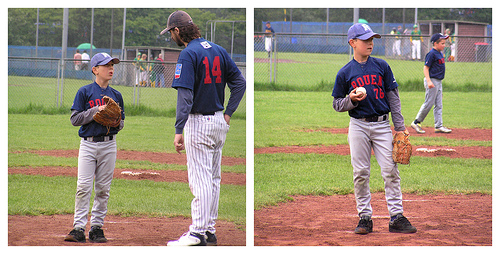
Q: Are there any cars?
A: No, there are no cars.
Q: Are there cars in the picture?
A: No, there are no cars.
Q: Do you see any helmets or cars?
A: No, there are no cars or helmets.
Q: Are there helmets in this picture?
A: No, there are no helmets.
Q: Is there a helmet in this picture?
A: No, there are no helmets.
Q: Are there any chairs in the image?
A: No, there are no chairs.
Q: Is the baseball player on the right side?
A: Yes, the player is on the right of the image.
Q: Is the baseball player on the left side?
A: No, the player is on the right of the image.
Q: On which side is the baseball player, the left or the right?
A: The player is on the right of the image.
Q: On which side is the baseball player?
A: The player is on the right of the image.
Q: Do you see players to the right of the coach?
A: Yes, there is a player to the right of the coach.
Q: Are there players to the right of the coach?
A: Yes, there is a player to the right of the coach.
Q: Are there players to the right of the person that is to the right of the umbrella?
A: Yes, there is a player to the right of the coach.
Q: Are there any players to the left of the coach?
A: No, the player is to the right of the coach.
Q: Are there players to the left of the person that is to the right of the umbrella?
A: No, the player is to the right of the coach.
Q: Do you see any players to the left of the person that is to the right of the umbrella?
A: No, the player is to the right of the coach.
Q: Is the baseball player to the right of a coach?
A: Yes, the player is to the right of a coach.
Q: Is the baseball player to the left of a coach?
A: No, the player is to the right of a coach.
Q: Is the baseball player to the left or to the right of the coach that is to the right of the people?
A: The player is to the right of the coach.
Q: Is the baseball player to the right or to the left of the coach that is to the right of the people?
A: The player is to the right of the coach.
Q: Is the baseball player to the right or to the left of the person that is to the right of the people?
A: The player is to the right of the coach.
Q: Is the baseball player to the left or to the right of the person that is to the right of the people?
A: The player is to the right of the coach.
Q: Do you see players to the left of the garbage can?
A: Yes, there is a player to the left of the garbage can.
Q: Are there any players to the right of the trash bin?
A: No, the player is to the left of the trash bin.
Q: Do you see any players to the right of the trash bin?
A: No, the player is to the left of the trash bin.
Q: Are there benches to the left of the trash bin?
A: No, there is a player to the left of the trash bin.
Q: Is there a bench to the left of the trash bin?
A: No, there is a player to the left of the trash bin.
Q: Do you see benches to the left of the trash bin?
A: No, there is a player to the left of the trash bin.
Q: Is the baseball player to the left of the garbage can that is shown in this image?
A: Yes, the player is to the left of the garbage can.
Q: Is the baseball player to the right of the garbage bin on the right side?
A: No, the player is to the left of the trash bin.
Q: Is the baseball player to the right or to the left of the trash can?
A: The player is to the left of the trash can.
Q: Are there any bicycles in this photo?
A: No, there are no bicycles.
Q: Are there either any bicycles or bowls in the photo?
A: No, there are no bicycles or bowls.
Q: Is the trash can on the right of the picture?
A: Yes, the trash can is on the right of the image.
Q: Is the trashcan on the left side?
A: No, the trashcan is on the right of the image.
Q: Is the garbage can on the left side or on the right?
A: The garbage can is on the right of the image.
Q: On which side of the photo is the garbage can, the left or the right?
A: The garbage can is on the right of the image.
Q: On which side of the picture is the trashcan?
A: The trashcan is on the right of the image.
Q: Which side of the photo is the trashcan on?
A: The trashcan is on the right of the image.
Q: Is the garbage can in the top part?
A: Yes, the garbage can is in the top of the image.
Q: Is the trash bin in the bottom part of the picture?
A: No, the trash bin is in the top of the image.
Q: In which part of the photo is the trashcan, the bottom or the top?
A: The trashcan is in the top of the image.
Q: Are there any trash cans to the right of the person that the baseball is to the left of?
A: Yes, there is a trash can to the right of the person.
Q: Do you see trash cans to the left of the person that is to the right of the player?
A: No, the trash can is to the right of the person.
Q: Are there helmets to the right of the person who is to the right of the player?
A: No, there is a trash can to the right of the person.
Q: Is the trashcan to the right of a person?
A: Yes, the trashcan is to the right of a person.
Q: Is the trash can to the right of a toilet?
A: No, the trash can is to the right of a person.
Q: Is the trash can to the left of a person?
A: No, the trash can is to the right of a person.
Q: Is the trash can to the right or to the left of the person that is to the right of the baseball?
A: The trash can is to the right of the person.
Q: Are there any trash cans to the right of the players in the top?
A: Yes, there is a trash can to the right of the players.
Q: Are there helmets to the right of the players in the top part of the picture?
A: No, there is a trash can to the right of the players.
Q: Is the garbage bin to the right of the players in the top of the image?
A: Yes, the garbage bin is to the right of the players.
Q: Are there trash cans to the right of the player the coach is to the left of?
A: Yes, there is a trash can to the right of the player.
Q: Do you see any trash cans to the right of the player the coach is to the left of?
A: Yes, there is a trash can to the right of the player.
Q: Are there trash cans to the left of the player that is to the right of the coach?
A: No, the trash can is to the right of the player.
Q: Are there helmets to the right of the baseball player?
A: No, there is a trash can to the right of the player.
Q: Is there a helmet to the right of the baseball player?
A: No, there is a trash can to the right of the player.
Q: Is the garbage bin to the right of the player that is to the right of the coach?
A: Yes, the garbage bin is to the right of the player.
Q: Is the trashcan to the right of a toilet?
A: No, the trashcan is to the right of the player.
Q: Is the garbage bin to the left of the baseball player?
A: No, the garbage bin is to the right of the player.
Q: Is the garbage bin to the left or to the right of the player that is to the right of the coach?
A: The garbage bin is to the right of the player.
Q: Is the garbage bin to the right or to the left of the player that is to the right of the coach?
A: The garbage bin is to the right of the player.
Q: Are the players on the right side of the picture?
A: Yes, the players are on the right of the image.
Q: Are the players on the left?
A: No, the players are on the right of the image.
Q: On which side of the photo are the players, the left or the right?
A: The players are on the right of the image.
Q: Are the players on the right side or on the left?
A: The players are on the right of the image.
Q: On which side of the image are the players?
A: The players are on the right of the image.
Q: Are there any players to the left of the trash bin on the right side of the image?
A: Yes, there are players to the left of the trash can.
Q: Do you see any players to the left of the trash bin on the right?
A: Yes, there are players to the left of the trash can.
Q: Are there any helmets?
A: No, there are no helmets.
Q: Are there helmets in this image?
A: No, there are no helmets.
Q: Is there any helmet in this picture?
A: No, there are no helmets.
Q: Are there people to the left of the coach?
A: Yes, there is a person to the left of the coach.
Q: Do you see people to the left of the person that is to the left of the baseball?
A: Yes, there is a person to the left of the coach.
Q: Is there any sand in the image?
A: Yes, there is sand.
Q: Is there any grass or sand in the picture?
A: Yes, there is sand.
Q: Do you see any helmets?
A: No, there are no helmets.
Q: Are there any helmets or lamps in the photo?
A: No, there are no helmets or lamps.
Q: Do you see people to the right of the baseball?
A: Yes, there is a person to the right of the baseball.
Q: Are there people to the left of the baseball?
A: No, the person is to the right of the baseball.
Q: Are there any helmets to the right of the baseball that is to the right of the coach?
A: No, there is a person to the right of the baseball.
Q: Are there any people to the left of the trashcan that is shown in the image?
A: Yes, there is a person to the left of the trashcan.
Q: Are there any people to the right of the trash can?
A: No, the person is to the left of the trash can.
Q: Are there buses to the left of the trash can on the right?
A: No, there is a person to the left of the trash can.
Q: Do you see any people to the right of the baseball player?
A: Yes, there is a person to the right of the player.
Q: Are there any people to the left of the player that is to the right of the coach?
A: No, the person is to the right of the player.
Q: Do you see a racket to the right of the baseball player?
A: No, there is a person to the right of the player.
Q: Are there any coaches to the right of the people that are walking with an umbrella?
A: Yes, there is a coach to the right of the people.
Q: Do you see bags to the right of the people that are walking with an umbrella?
A: No, there is a coach to the right of the people.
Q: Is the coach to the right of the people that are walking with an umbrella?
A: Yes, the coach is to the right of the people.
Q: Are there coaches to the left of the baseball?
A: Yes, there is a coach to the left of the baseball.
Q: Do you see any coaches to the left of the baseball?
A: Yes, there is a coach to the left of the baseball.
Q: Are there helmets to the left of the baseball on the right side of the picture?
A: No, there is a coach to the left of the baseball.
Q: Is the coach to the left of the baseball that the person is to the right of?
A: Yes, the coach is to the left of the baseball.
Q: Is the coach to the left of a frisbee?
A: No, the coach is to the left of the baseball.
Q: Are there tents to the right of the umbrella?
A: No, there is a coach to the right of the umbrella.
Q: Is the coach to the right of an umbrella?
A: Yes, the coach is to the right of an umbrella.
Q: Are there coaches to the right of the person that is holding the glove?
A: Yes, there is a coach to the right of the person.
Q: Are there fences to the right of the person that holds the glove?
A: No, there is a coach to the right of the person.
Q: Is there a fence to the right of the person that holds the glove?
A: No, there is a coach to the right of the person.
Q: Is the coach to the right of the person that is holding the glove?
A: Yes, the coach is to the right of the person.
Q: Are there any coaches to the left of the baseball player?
A: Yes, there is a coach to the left of the player.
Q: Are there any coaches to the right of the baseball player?
A: No, the coach is to the left of the player.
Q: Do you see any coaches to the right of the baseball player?
A: No, the coach is to the left of the player.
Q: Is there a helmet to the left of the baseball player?
A: No, there is a coach to the left of the player.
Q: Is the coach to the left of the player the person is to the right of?
A: Yes, the coach is to the left of the player.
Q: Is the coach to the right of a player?
A: No, the coach is to the left of a player.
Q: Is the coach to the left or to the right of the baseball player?
A: The coach is to the left of the player.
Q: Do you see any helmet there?
A: No, there are no helmets.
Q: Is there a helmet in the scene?
A: No, there are no helmets.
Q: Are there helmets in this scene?
A: No, there are no helmets.